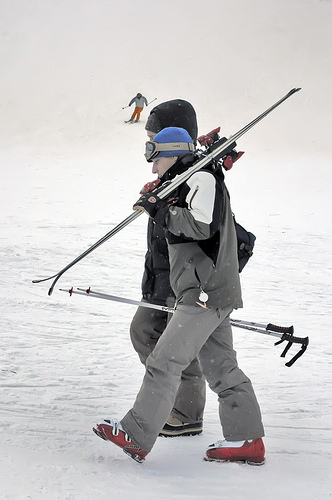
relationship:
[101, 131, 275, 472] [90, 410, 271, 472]
man wearing boots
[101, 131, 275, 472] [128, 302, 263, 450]
man wearing pants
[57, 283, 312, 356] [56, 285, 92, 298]
ski poles have tops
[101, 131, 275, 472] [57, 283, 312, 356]
man carrying ski poles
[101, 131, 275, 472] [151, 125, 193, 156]
man wearing hat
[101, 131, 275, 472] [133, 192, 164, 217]
man wearing gloves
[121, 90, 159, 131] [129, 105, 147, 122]
person wearing pants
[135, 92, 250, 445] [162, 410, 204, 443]
man wearing boots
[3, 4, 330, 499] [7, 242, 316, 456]
snow has tracks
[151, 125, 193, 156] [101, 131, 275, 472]
hat on man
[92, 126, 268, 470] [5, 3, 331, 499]
man on ground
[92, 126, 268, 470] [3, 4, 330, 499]
man walking on snow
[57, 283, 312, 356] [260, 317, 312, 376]
ski poles have handles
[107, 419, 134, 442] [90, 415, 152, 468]
clamps on boot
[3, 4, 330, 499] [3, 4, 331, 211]
snow on hill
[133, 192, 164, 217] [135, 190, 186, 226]
glove on hand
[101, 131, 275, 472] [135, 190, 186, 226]
man has hand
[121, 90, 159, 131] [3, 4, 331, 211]
person skiing down hill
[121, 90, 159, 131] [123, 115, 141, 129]
person has skis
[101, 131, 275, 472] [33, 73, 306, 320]
man holding skis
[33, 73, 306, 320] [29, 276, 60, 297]
skis have tips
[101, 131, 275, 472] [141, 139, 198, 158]
man wearing goggles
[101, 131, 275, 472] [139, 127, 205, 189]
man has head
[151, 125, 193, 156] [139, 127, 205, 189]
hat on head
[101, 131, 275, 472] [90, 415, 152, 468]
man wearing boot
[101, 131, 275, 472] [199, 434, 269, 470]
man wearing boot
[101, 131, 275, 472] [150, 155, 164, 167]
man has eye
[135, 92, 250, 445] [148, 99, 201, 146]
man wearing hat